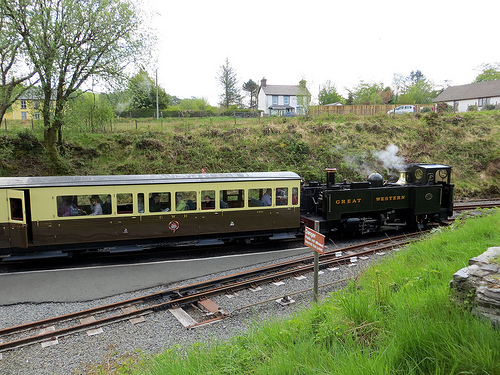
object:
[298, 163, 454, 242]
engine train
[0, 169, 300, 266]
passenger car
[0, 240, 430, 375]
train tracks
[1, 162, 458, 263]
train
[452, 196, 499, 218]
train tracks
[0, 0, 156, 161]
tree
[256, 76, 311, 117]
house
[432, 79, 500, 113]
house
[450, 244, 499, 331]
rock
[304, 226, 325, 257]
sign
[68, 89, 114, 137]
tree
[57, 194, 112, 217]
window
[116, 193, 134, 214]
window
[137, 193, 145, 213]
window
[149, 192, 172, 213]
window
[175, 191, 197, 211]
window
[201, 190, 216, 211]
window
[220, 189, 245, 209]
window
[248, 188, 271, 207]
window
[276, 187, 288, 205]
window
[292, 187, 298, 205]
window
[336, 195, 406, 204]
great western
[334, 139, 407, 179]
smoke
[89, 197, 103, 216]
passengers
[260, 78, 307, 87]
two chimneys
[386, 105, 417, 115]
car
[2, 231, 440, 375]
gravel road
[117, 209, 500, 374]
grass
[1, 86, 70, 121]
house